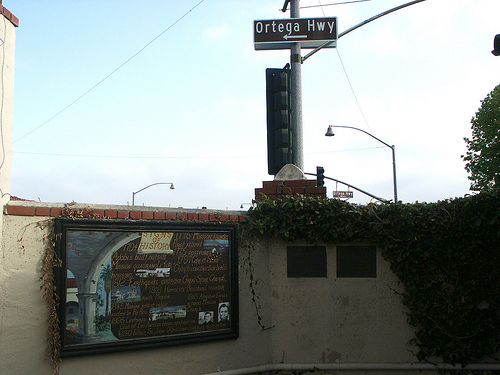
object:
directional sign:
[251, 15, 339, 50]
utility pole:
[283, 0, 304, 171]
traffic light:
[264, 69, 296, 176]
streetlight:
[323, 125, 337, 138]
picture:
[47, 213, 242, 363]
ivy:
[235, 238, 263, 335]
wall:
[268, 235, 499, 374]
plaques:
[333, 244, 376, 279]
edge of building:
[3, 201, 248, 228]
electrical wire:
[12, 0, 207, 146]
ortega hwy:
[253, 18, 337, 33]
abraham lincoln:
[216, 301, 232, 326]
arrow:
[281, 33, 309, 42]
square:
[283, 244, 326, 279]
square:
[333, 243, 377, 278]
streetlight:
[167, 183, 176, 190]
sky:
[0, 1, 499, 212]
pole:
[130, 194, 136, 207]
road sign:
[331, 191, 354, 199]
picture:
[214, 298, 234, 331]